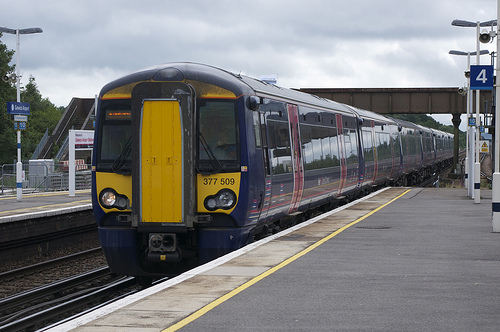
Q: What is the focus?
A: Train arriving at stop.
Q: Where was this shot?
A: Train stop.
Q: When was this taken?
A: Dayitme.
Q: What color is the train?
A: Blue, red, yellow.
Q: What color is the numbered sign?
A: Blue.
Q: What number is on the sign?
A: 4.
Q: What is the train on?
A: Train tracks.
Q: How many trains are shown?
A: 1.